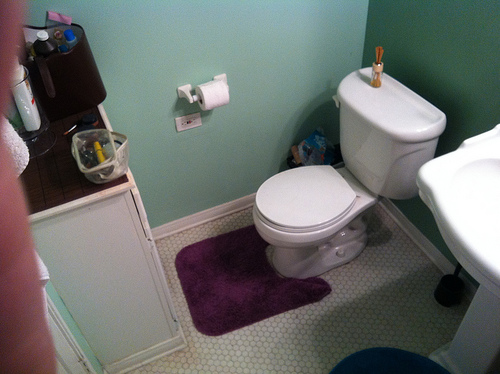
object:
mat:
[330, 347, 454, 374]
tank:
[332, 67, 447, 200]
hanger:
[177, 73, 227, 103]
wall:
[23, 0, 500, 287]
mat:
[175, 223, 333, 336]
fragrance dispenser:
[370, 46, 384, 87]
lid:
[254, 165, 357, 233]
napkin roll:
[195, 80, 230, 111]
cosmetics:
[80, 133, 122, 169]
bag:
[71, 129, 129, 184]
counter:
[17, 103, 136, 223]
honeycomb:
[246, 338, 301, 364]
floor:
[114, 203, 499, 374]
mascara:
[93, 141, 106, 165]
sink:
[451, 157, 499, 268]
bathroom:
[0, 0, 500, 374]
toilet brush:
[434, 262, 464, 307]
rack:
[428, 283, 499, 374]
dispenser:
[177, 84, 194, 104]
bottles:
[2, 55, 42, 131]